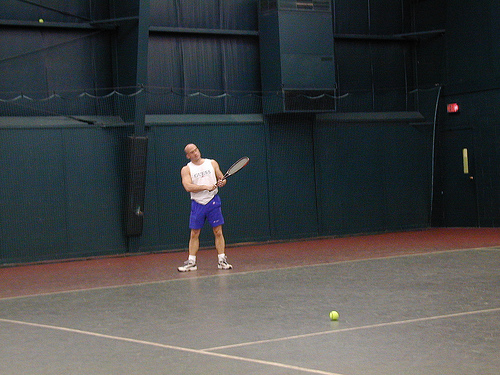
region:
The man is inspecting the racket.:
[151, 111, 271, 281]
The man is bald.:
[176, 135, 206, 170]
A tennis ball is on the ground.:
[315, 295, 350, 340]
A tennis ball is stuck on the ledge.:
[25, 10, 50, 35]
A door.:
[440, 125, 490, 225]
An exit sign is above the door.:
[436, 92, 491, 227]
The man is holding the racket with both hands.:
[170, 125, 250, 280]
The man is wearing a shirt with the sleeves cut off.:
[175, 131, 230, 276]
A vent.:
[265, 75, 341, 130]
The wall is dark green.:
[10, 15, 430, 265]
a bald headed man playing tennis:
[178, 142, 250, 270]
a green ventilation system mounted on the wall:
[256, 1, 337, 116]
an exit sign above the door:
[445, 101, 460, 116]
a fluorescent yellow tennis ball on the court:
[329, 310, 338, 322]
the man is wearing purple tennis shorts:
[188, 198, 224, 226]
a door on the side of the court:
[438, 126, 476, 227]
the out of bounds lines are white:
[1, 316, 364, 374]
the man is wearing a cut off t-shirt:
[180, 158, 217, 203]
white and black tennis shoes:
[176, 259, 198, 271]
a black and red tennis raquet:
[207, 153, 251, 192]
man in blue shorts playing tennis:
[47, 91, 462, 373]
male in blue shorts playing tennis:
[44, 82, 459, 373]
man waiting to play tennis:
[26, 81, 451, 373]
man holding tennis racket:
[28, 84, 468, 371]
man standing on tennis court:
[21, 88, 476, 368]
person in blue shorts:
[62, 91, 371, 311]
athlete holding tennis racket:
[66, 111, 439, 336]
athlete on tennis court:
[53, 105, 418, 302]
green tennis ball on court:
[135, 270, 495, 370]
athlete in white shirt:
[60, 110, 466, 368]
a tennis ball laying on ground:
[308, 293, 359, 330]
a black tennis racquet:
[206, 143, 265, 205]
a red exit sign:
[432, 93, 474, 130]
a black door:
[439, 129, 492, 240]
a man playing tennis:
[163, 128, 265, 293]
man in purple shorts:
[178, 196, 245, 233]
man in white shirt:
[175, 151, 230, 209]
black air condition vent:
[261, 0, 357, 147]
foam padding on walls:
[0, 126, 170, 283]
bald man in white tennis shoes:
[137, 116, 289, 301]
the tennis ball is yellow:
[289, 299, 379, 353]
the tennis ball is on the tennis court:
[289, 311, 383, 339]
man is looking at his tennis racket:
[175, 146, 273, 206]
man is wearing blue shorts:
[181, 191, 251, 237]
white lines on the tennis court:
[120, 316, 303, 374]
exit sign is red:
[443, 98, 474, 125]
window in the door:
[456, 145, 482, 187]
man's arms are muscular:
[173, 153, 260, 204]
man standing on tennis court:
[173, 136, 267, 293]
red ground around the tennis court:
[268, 230, 479, 245]